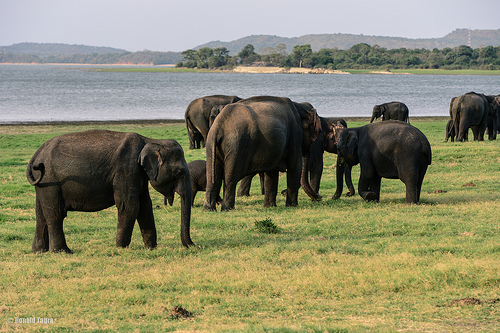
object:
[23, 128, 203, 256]
elephant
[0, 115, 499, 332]
grass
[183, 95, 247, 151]
elephant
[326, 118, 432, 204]
elephant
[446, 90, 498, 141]
elephant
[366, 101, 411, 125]
elephant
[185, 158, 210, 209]
elephant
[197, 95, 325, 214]
elephant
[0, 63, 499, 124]
water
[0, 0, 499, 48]
sky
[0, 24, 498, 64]
hills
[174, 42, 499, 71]
trees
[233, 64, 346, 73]
sand